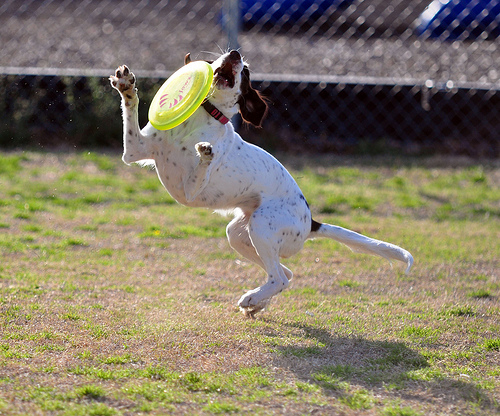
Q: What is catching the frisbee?
A: A black and white dog.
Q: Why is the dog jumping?
A: To catch frisbee.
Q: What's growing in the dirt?
A: Grass.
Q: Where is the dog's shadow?
A: On the dirt and grass.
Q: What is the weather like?
A: Clear and sunny.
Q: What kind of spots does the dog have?
A: Small black spots.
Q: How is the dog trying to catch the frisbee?
A: With its mouth.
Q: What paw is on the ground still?
A: Back right.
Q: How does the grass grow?
A: Patches.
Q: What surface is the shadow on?
A: Dirt and grass.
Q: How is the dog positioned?
A: In the air.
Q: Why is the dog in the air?
A: Catching a Frisbee.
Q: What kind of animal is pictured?
A: Dog.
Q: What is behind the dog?
A: A fence.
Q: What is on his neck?
A: A red collar.